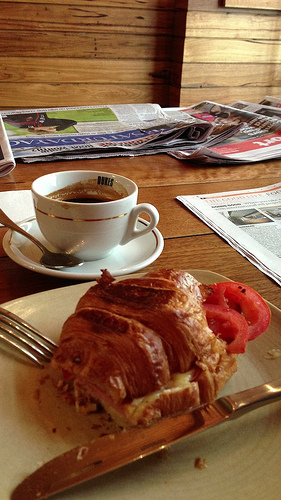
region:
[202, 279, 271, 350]
two slices of tomatoes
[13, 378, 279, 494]
a butter knife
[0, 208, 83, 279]
a spoon on a plate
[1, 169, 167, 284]
a cup and saucer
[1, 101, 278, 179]
a row of newspapers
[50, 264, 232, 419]
a sandwich on a plate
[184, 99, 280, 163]
a sports paper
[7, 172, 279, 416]
food and tea on a wood table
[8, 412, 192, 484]
a dirty butter knife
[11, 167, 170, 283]
cup and saucer with gold ring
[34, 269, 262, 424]
a tomato and cheese crossaint sits on a white plate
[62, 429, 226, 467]
a metal fork lays on a plate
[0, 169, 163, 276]
a cup of coffee sits on a wooden table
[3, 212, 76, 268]
a spoon rests on a white saucer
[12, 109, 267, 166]
newpapers are scattered across a table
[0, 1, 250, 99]
a wall is made of wood panels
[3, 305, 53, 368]
a fork next to a half-eaten sandwich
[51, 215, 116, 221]
gold trims the edge of a teacup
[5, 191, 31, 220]
a white napkin is next to a cup of coffee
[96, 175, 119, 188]
words are stenciled inside a teacup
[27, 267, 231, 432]
bread with high fat content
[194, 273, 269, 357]
two tomato slices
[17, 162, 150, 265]
coffee made with a European coffee maker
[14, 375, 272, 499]
a piece of stainless flatware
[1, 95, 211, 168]
a used newspaper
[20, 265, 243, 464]
a breakfast croissant with some meat filling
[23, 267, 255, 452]
a meal high in carbohydrates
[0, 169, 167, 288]
a gilded cup and saucer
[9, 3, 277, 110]
a wall made of wood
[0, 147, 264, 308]
a wooden table top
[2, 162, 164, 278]
white cup and saucer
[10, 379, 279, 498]
stainless steel butter knife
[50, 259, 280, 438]
half eaten croissant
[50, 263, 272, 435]
croissant with tomato slice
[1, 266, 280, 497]
fork resting on plate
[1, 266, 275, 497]
cream ceramic plate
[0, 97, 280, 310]
newspapers on table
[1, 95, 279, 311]
wooden table under papers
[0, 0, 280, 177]
wooden wall next to papers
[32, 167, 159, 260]
coffee in white cup and saucer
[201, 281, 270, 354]
tomato slices in a sandwich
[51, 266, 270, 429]
a half eaten croissant sandwich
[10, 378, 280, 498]
the dinner knife has a bronze tint in color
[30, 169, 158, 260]
a coffee cup sits on a matching saucer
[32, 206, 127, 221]
there is a gold stripe around the coffee cup and saucer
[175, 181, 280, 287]
the newspaper is on the wooden table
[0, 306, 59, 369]
the fork is sitting on the plate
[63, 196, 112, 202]
there is black coffee in the coffee cup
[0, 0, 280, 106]
the wall behind the table is made of wood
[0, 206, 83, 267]
the spoon is sitting on the coffee saucer